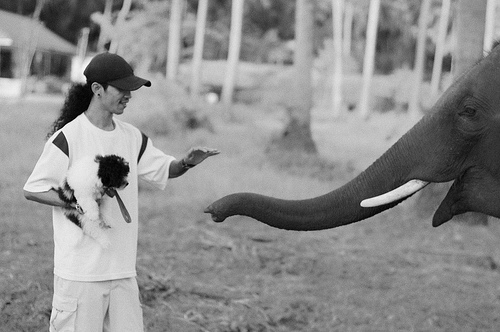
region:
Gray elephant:
[204, 38, 498, 236]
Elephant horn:
[358, 176, 425, 204]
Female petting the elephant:
[20, 49, 217, 329]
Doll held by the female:
[58, 153, 129, 238]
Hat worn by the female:
[82, 49, 150, 93]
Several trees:
[0, 2, 488, 179]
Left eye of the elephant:
[455, 93, 485, 127]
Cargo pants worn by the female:
[45, 276, 142, 330]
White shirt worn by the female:
[24, 113, 172, 277]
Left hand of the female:
[168, 143, 219, 178]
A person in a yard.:
[15, 63, 245, 330]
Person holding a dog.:
[7, 40, 219, 326]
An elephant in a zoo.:
[190, 1, 495, 326]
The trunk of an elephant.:
[200, 142, 421, 232]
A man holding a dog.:
[26, 52, 237, 327]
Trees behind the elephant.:
[128, 3, 493, 170]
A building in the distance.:
[0, 6, 81, 103]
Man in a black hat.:
[19, 47, 186, 328]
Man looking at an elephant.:
[7, 28, 499, 318]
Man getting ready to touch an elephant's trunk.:
[11, 49, 498, 301]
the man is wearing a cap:
[83, 52, 150, 92]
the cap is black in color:
[82, 47, 148, 92]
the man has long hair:
[49, 80, 100, 135]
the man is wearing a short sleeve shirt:
[32, 109, 180, 283]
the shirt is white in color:
[38, 113, 176, 298]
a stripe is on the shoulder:
[50, 131, 72, 156]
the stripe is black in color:
[50, 130, 70, 158]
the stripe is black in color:
[137, 130, 147, 160]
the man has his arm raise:
[149, 129, 219, 189]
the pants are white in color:
[48, 270, 150, 328]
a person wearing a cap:
[21, 42, 218, 330]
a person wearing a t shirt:
[0, 45, 240, 325]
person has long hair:
[14, 51, 221, 331]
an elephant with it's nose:
[205, 13, 497, 240]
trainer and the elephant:
[12, 7, 497, 330]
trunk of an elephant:
[352, 158, 449, 217]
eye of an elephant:
[449, 93, 489, 134]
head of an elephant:
[200, 19, 499, 241]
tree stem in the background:
[249, 1, 343, 158]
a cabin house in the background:
[0, 10, 115, 102]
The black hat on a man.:
[83, 51, 151, 94]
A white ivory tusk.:
[359, 169, 428, 207]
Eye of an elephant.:
[455, 105, 479, 117]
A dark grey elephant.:
[204, 42, 499, 232]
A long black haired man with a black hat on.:
[24, 50, 221, 330]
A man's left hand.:
[183, 143, 221, 170]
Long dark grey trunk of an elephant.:
[203, 130, 435, 232]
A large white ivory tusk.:
[358, 177, 430, 209]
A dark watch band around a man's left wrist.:
[178, 158, 197, 170]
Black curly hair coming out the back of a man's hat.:
[48, 80, 91, 140]